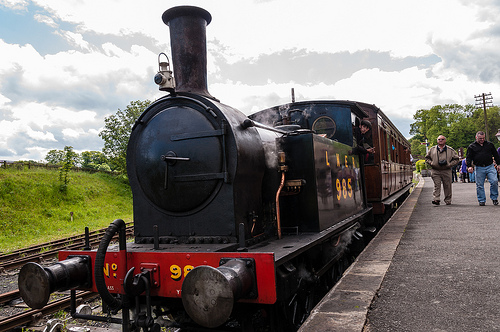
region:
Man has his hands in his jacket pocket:
[426, 157, 456, 172]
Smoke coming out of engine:
[254, 99, 281, 167]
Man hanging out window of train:
[353, 115, 380, 156]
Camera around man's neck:
[432, 143, 452, 170]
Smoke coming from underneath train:
[336, 224, 364, 249]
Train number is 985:
[333, 173, 359, 203]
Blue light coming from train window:
[391, 139, 399, 150]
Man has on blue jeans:
[473, 163, 498, 198]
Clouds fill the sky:
[2, 0, 498, 127]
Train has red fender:
[56, 248, 279, 307]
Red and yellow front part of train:
[54, 243, 278, 308]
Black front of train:
[129, 2, 374, 231]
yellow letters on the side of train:
[321, 145, 359, 207]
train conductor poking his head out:
[351, 120, 373, 155]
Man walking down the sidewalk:
[421, 128, 463, 216]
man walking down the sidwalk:
[464, 119, 498, 208]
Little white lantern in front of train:
[151, 53, 173, 90]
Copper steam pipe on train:
[263, 140, 290, 241]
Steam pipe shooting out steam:
[266, 143, 291, 237]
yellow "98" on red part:
[169, 265, 201, 282]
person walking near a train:
[419, 129, 462, 212]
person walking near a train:
[466, 128, 497, 212]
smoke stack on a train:
[158, 2, 216, 97]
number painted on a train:
[165, 261, 182, 281]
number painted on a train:
[331, 175, 343, 204]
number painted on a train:
[340, 174, 349, 201]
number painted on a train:
[345, 175, 355, 197]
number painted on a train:
[180, 259, 196, 279]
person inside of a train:
[356, 111, 381, 158]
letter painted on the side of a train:
[322, 147, 332, 167]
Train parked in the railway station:
[18, 0, 333, 277]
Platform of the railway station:
[411, 206, 488, 296]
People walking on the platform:
[425, 130, 499, 202]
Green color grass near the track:
[10, 170, 53, 216]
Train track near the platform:
[23, 235, 58, 257]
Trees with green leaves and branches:
[426, 106, 471, 131]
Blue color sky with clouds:
[23, 13, 116, 98]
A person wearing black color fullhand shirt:
[469, 143, 494, 163]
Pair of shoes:
[431, 194, 452, 211]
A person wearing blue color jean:
[476, 176, 497, 191]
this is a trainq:
[222, 111, 418, 316]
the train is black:
[81, 43, 343, 327]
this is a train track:
[20, 239, 52, 287]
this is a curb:
[237, 266, 346, 330]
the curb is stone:
[318, 275, 353, 327]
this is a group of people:
[386, 126, 453, 164]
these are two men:
[387, 90, 492, 237]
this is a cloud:
[292, 54, 359, 81]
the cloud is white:
[326, 16, 386, 118]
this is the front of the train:
[111, 89, 231, 184]